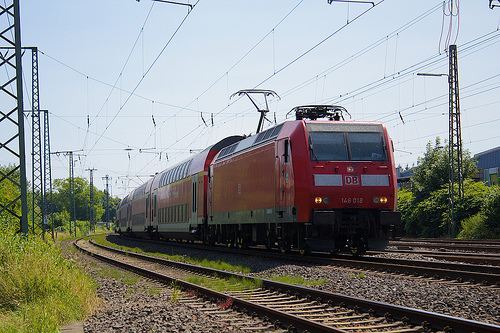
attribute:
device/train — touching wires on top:
[228, 83, 278, 131]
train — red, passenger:
[104, 97, 406, 263]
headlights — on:
[308, 192, 391, 215]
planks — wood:
[234, 284, 369, 321]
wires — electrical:
[2, 3, 499, 119]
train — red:
[100, 113, 406, 267]